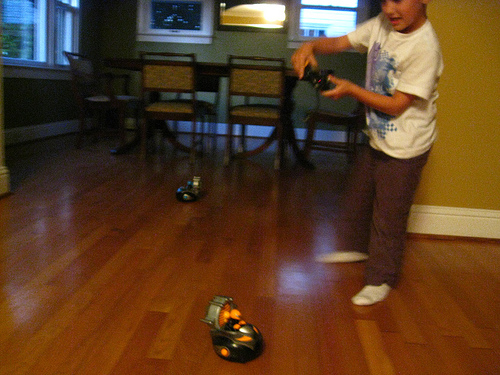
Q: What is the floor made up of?
A: Wood.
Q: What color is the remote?
A: Black.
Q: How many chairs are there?
A: Two.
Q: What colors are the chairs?
A: Brown and tan.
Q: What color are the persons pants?
A: Brown.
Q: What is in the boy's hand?
A: A remote controller.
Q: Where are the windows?
A: At the back and left of the photo.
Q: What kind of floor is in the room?
A: Hardwood.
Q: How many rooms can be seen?
A: 2.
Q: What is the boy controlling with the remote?
A: A toy car.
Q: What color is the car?
A: Orange, gray and black.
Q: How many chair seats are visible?
A: 4.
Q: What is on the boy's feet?
A: Socks.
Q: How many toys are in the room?
A: 2.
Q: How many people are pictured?
A: One.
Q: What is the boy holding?
A: A remote.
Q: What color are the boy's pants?
A: Brown.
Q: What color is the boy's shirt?
A: White.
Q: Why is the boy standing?
A: Playing cars.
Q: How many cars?
A: 2.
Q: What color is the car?
A: Yellow.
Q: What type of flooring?
A: Wood.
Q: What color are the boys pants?
A: Brown.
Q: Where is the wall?
A: Behind the boy.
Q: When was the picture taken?
A: Daytime.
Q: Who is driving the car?
A: The boy.